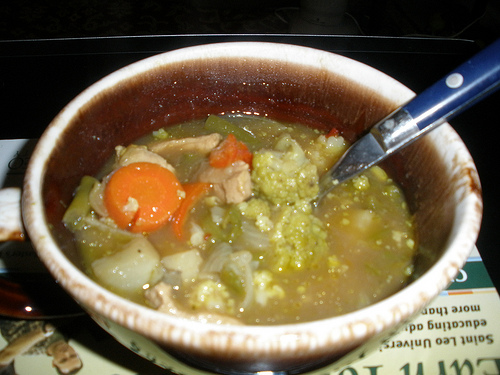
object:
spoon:
[323, 49, 497, 178]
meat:
[205, 162, 252, 204]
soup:
[277, 254, 349, 307]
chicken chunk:
[193, 157, 262, 206]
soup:
[321, 220, 415, 292]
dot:
[434, 67, 480, 96]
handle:
[409, 40, 498, 135]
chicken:
[143, 132, 223, 158]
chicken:
[113, 142, 174, 174]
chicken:
[145, 282, 245, 329]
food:
[244, 198, 325, 272]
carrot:
[208, 140, 252, 168]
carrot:
[167, 184, 218, 235]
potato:
[93, 236, 163, 291]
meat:
[199, 160, 254, 204]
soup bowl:
[21, 33, 485, 372]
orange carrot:
[101, 160, 186, 235]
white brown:
[407, 115, 480, 372]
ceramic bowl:
[18, 41, 483, 373]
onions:
[236, 218, 266, 247]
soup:
[334, 179, 412, 235]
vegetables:
[256, 202, 358, 271]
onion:
[202, 240, 234, 274]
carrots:
[88, 137, 283, 224]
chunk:
[193, 161, 254, 203]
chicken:
[193, 161, 256, 204]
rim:
[22, 41, 110, 358]